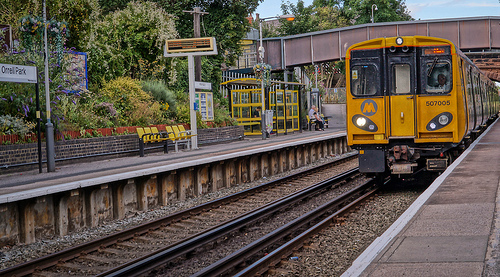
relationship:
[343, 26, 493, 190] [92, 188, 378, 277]
train on rail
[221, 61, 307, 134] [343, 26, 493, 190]
area by train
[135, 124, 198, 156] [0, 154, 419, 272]
bench are by tracks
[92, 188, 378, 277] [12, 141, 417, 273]
rail has gravel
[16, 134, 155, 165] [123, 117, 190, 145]
wall by bench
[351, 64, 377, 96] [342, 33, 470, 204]
window on train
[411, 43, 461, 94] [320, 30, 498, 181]
window on train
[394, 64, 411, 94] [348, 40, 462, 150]
window on train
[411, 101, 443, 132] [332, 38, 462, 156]
light on train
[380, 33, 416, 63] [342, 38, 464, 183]
light on train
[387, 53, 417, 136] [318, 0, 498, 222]
door on train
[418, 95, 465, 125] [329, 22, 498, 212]
numbers on train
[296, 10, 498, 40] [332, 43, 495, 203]
bridge over train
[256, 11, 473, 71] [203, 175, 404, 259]
walkway over tracks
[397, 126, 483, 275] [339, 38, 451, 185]
platform by train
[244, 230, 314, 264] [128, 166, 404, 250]
rail on tracks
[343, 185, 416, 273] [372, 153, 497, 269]
line on platform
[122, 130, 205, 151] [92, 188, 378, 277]
seats by rail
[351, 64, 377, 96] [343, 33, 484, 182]
window built into train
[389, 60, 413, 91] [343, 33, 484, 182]
window built into train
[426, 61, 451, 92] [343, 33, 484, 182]
window built into train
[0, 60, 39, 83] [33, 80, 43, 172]
sign mounted on pole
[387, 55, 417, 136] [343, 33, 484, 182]
door leading to train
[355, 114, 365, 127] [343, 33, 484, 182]
headlight mounted on train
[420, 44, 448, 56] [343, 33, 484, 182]
destination sign lit up on train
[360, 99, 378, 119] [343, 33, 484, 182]
decal stuck on train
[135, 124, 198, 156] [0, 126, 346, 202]
bench sitting on sidewalk